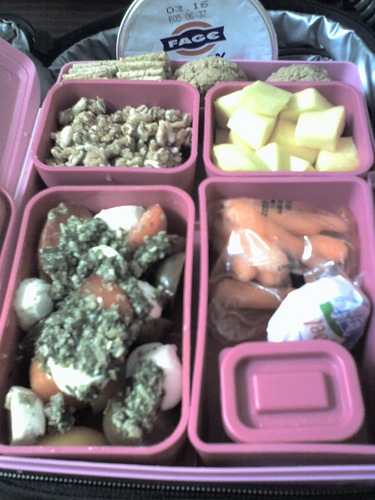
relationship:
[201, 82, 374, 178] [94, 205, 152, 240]
container holding mozzarella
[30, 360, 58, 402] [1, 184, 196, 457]
tomato in container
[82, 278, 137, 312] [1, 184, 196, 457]
tomato in container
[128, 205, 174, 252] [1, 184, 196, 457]
tomato in container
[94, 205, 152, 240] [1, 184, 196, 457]
mozzarella in container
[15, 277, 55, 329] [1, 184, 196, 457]
mozzarella in container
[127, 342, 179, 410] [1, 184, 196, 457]
mozzarella in container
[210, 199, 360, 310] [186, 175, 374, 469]
carrots in container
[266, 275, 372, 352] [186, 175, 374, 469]
cheese in container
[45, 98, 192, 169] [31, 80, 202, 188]
walnuts in container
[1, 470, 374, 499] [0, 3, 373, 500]
zipper on cooler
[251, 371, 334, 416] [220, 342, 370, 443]
shape on container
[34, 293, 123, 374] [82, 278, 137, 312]
pesto on tomato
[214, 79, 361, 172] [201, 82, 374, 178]
pineapple in container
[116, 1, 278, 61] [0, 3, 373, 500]
yogurt in cooler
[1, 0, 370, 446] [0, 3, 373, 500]
lunch in cooler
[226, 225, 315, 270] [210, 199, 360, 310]
reflection on carrots